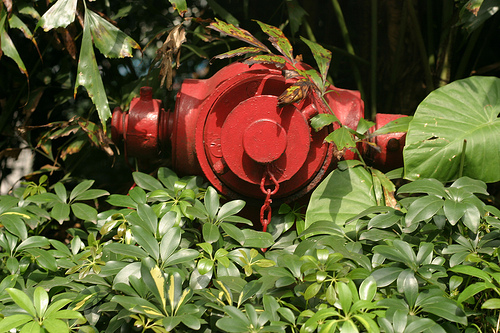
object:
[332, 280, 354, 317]
leaf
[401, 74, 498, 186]
leaf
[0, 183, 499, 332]
bush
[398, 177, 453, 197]
leaf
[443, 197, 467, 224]
leaf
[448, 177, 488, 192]
leaf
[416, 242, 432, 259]
leaf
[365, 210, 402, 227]
leaf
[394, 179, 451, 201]
leaf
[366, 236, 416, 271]
leaf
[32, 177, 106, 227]
leaves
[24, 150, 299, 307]
plant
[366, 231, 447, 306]
leaves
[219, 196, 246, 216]
leaf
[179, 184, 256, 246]
plant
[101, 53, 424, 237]
fire hydrant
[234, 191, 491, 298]
leaf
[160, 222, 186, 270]
leaf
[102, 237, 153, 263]
leaf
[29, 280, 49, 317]
leaf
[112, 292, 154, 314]
leaf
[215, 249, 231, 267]
leaf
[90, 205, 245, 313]
leaves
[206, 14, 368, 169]
branch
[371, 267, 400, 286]
leaf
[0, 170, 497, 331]
plant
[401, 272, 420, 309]
leaf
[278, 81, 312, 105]
spots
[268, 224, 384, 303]
leaves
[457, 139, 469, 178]
branch